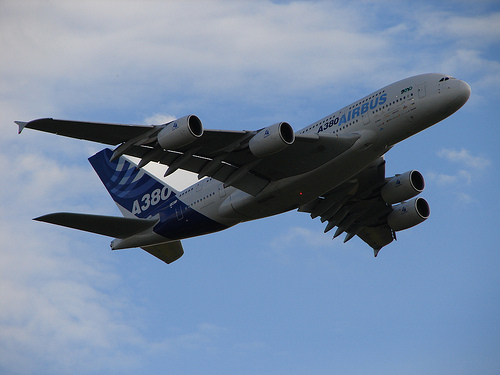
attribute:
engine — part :
[154, 115, 205, 150]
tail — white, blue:
[86, 144, 185, 224]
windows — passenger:
[367, 97, 422, 114]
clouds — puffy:
[120, 11, 238, 55]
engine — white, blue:
[241, 130, 308, 174]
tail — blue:
[30, 195, 210, 299]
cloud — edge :
[196, 312, 268, 355]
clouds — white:
[178, 23, 343, 74]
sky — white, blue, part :
[3, 0, 497, 371]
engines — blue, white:
[155, 113, 430, 230]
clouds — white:
[145, 22, 340, 89]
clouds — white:
[139, 36, 259, 76]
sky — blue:
[331, 289, 448, 345]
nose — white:
[436, 74, 471, 104]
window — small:
[386, 82, 423, 107]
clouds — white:
[439, 146, 486, 181]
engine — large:
[378, 166, 461, 226]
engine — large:
[148, 114, 213, 154]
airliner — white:
[17, 69, 469, 273]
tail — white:
[83, 147, 180, 216]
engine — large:
[136, 110, 313, 177]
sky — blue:
[0, 13, 413, 95]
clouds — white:
[1, 12, 400, 66]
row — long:
[361, 89, 415, 117]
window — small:
[413, 84, 426, 94]